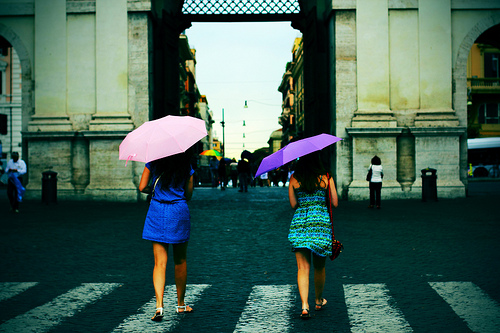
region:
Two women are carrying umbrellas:
[74, 89, 486, 271]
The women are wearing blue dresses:
[64, 132, 379, 232]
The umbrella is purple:
[226, 107, 352, 185]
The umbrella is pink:
[115, 118, 214, 186]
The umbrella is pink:
[84, 107, 273, 204]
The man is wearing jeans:
[8, 165, 76, 221]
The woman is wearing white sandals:
[136, 286, 211, 330]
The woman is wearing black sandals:
[283, 297, 363, 313]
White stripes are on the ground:
[19, 215, 486, 320]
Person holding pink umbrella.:
[115, 125, 218, 165]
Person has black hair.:
[158, 152, 195, 202]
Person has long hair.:
[141, 162, 211, 187]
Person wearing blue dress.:
[153, 167, 195, 261]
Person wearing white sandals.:
[141, 293, 231, 315]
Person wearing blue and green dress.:
[284, 191, 355, 258]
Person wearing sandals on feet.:
[278, 272, 359, 319]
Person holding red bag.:
[331, 188, 357, 288]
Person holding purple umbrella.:
[252, 120, 360, 157]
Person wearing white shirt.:
[372, 157, 384, 197]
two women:
[149, 162, 335, 309]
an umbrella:
[124, 115, 202, 165]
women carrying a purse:
[330, 236, 345, 261]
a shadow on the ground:
[238, 283, 285, 332]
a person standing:
[364, 158, 391, 207]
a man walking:
[1, 150, 33, 209]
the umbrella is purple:
[260, 128, 335, 163]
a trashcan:
[420, 165, 441, 199]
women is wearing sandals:
[296, 305, 311, 318]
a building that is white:
[26, 23, 133, 127]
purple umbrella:
[251, 131, 337, 177]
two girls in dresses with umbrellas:
[119, 112, 340, 316]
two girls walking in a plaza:
[1, 115, 498, 330]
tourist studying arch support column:
[367, 155, 385, 210]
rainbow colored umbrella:
[199, 148, 222, 156]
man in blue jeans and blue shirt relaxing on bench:
[4, 151, 27, 201]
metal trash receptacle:
[421, 167, 438, 202]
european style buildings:
[269, 36, 305, 151]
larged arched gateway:
[150, 2, 335, 198]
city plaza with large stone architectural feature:
[1, 0, 496, 332]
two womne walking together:
[120, 102, 340, 318]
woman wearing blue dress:
[129, 152, 203, 320]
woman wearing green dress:
[278, 166, 347, 319]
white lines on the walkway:
[4, 277, 495, 332]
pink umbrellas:
[113, 107, 205, 162]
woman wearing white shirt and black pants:
[362, 157, 387, 205]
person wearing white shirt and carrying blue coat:
[4, 152, 28, 206]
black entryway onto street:
[153, 5, 335, 192]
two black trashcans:
[40, 168, 443, 205]